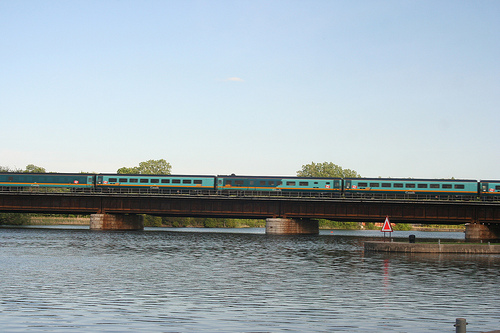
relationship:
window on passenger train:
[428, 177, 440, 193] [2, 167, 497, 205]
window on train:
[356, 182, 368, 187] [2, 170, 497, 202]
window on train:
[453, 182, 465, 191] [4, 167, 499, 197]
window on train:
[428, 183, 440, 189] [6, 155, 498, 203]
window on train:
[286, 179, 319, 189] [0, 172, 499, 204]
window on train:
[368, 180, 380, 191] [2, 170, 497, 202]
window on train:
[392, 181, 404, 192] [4, 167, 499, 197]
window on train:
[368, 183, 380, 188] [0, 160, 497, 215]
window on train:
[356, 182, 368, 187] [4, 177, 499, 194]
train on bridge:
[89, 146, 497, 211] [111, 174, 473, 259]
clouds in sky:
[0, 0, 499, 181] [2, 3, 499, 173]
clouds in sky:
[7, 144, 57, 165] [2, 3, 499, 173]